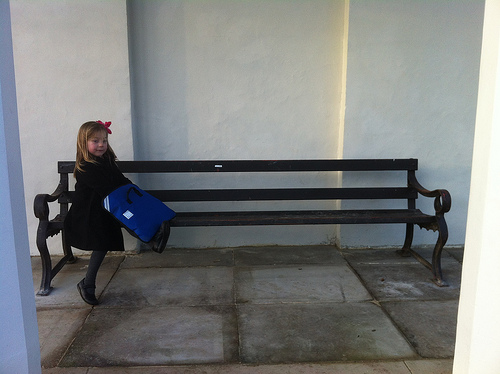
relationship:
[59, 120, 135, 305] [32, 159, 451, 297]
girl sitting on bench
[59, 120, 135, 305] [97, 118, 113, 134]
girl wearing ribbon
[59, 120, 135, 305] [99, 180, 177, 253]
girl carrying bag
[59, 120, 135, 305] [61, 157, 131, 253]
girl wearing jacket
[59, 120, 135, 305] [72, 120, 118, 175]
girl has hair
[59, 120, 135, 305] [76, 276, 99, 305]
girl wearing shoe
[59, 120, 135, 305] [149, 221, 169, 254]
girl wearing shoe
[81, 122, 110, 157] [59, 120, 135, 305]
head on top of girl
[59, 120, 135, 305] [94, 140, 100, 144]
girl has eye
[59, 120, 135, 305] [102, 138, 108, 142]
girl has eye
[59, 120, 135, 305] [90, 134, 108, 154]
girl has face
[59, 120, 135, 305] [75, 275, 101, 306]
girl has foot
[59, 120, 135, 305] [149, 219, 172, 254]
girl has foot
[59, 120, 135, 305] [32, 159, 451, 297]
girl near bench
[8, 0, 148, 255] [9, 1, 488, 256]
side part of wall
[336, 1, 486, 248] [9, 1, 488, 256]
side part of wall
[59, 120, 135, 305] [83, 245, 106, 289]
girl wearing tights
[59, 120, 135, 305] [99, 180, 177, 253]
girl holding bag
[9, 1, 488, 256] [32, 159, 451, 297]
wall behind bench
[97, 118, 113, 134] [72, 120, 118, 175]
ribbon in hair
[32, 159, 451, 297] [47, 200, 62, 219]
bench has opening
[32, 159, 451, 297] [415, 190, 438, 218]
bench has opening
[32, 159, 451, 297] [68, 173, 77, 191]
bench has opening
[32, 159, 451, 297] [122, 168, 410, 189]
bench has opening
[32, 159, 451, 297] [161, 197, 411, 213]
bench has opening